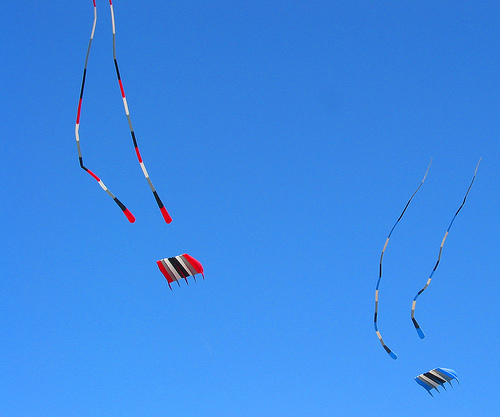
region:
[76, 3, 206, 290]
a kite flying high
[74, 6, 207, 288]
a red, white, blue, and grey kite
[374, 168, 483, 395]
a blue kite flying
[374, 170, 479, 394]
a blue, grey, white, and dark blue kite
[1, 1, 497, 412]
a blue sky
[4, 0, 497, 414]
a blue sky with two kites flying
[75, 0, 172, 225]
the long tail of a red kite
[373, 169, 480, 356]
the long tail of a blue kite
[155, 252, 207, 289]
the head of a red kite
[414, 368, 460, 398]
the head of a blue kite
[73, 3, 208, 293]
A kite in the sky.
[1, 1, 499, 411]
A clear blue sky.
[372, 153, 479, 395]
A blue kite in the sky.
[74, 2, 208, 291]
A red kite in the sky.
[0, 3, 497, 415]
A bright blue sky.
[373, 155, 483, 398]
A blue kite in the air.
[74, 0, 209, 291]
A striped kite in the sky.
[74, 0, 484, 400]
Two kites in the sky.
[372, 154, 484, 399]
One kite in the sky.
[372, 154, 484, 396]
Blue black and white kite in the air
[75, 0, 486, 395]
Two kites with long tails in the air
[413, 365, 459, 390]
Rectangle top of kite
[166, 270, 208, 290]
Long skinny points on top of kite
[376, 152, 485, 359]
Double tail on back of kite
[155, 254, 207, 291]
Black stripe in middle of kite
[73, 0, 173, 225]
White gray black and white tail of kite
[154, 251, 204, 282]
Red stripes on edge of kite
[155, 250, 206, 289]
White stripes next to black stripe on kite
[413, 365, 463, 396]
Blue stripes on edge of kite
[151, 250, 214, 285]
The main part of the red kite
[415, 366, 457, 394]
The main part of the blue kite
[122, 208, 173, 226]
The first red stripes on the tail of the red kite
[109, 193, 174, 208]
The first black stripes on the tail of the black stripe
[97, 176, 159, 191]
The first gray stripe on the tails on the red kite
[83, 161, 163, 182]
The first white stripes on the tail of the red kite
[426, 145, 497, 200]
The white tips of the blue kite stands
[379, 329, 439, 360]
The blue base of the blue kite tails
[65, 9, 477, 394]
Two kites flying in the sky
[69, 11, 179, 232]
The two kite tails of the red kite